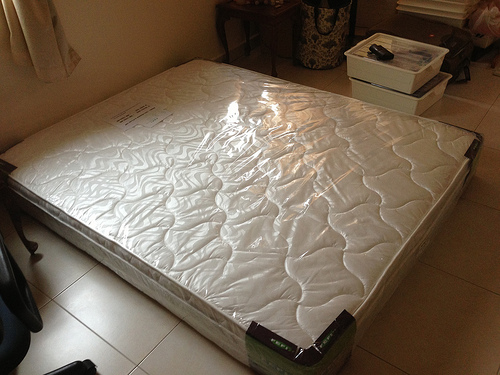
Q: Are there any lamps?
A: No, there are no lamps.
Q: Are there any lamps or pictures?
A: No, there are no lamps or pictures.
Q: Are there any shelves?
A: No, there are no shelves.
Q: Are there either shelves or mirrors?
A: No, there are no shelves or mirrors.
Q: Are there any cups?
A: No, there are no cups.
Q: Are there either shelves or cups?
A: No, there are no cups or shelves.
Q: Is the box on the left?
A: No, the box is on the right of the image.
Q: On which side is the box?
A: The box is on the right of the image.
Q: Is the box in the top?
A: Yes, the box is in the top of the image.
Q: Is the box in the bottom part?
A: No, the box is in the top of the image.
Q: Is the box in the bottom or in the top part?
A: The box is in the top of the image.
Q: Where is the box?
A: The box is on the floor.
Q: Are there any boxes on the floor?
A: Yes, there is a box on the floor.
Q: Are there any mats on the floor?
A: No, there is a box on the floor.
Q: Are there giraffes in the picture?
A: No, there are no giraffes.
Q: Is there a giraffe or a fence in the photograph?
A: No, there are no giraffes or fences.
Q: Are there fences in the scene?
A: No, there are no fences.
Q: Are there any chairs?
A: Yes, there is a chair.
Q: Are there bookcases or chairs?
A: Yes, there is a chair.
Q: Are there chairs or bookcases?
A: Yes, there is a chair.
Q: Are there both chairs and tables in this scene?
A: Yes, there are both a chair and a table.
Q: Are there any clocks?
A: No, there are no clocks.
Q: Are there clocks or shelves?
A: No, there are no clocks or shelves.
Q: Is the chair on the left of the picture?
A: Yes, the chair is on the left of the image.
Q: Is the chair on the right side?
A: No, the chair is on the left of the image.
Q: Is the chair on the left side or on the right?
A: The chair is on the left of the image.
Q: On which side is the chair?
A: The chair is on the left of the image.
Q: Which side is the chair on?
A: The chair is on the left of the image.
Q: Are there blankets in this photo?
A: No, there are no blankets.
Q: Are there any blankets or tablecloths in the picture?
A: No, there are no blankets or tablecloths.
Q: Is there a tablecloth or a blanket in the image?
A: No, there are no blankets or tablecloths.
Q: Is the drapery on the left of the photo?
A: Yes, the drapery is on the left of the image.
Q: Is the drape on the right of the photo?
A: No, the drape is on the left of the image.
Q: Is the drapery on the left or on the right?
A: The drapery is on the left of the image.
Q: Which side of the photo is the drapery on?
A: The drapery is on the left of the image.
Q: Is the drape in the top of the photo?
A: Yes, the drape is in the top of the image.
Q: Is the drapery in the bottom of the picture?
A: No, the drapery is in the top of the image.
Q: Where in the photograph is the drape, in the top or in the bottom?
A: The drape is in the top of the image.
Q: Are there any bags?
A: Yes, there is a bag.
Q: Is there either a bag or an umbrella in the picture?
A: Yes, there is a bag.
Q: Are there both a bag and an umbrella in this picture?
A: No, there is a bag but no umbrellas.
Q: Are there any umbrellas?
A: No, there are no umbrellas.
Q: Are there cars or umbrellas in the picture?
A: No, there are no umbrellas or cars.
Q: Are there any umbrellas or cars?
A: No, there are no umbrellas or cars.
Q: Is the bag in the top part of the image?
A: Yes, the bag is in the top of the image.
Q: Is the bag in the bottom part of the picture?
A: No, the bag is in the top of the image.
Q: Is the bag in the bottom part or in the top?
A: The bag is in the top of the image.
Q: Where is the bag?
A: The bag is on the floor.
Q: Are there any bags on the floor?
A: Yes, there is a bag on the floor.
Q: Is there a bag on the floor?
A: Yes, there is a bag on the floor.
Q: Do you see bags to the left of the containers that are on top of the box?
A: Yes, there is a bag to the left of the containers.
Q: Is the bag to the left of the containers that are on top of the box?
A: Yes, the bag is to the left of the containers.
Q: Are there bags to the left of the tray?
A: Yes, there is a bag to the left of the tray.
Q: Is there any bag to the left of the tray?
A: Yes, there is a bag to the left of the tray.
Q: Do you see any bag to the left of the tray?
A: Yes, there is a bag to the left of the tray.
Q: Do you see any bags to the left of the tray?
A: Yes, there is a bag to the left of the tray.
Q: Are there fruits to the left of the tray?
A: No, there is a bag to the left of the tray.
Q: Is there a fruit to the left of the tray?
A: No, there is a bag to the left of the tray.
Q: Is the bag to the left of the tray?
A: Yes, the bag is to the left of the tray.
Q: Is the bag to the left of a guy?
A: No, the bag is to the left of the tray.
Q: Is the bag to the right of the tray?
A: No, the bag is to the left of the tray.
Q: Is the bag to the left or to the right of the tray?
A: The bag is to the left of the tray.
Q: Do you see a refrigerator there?
A: No, there are no refrigerators.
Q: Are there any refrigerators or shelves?
A: No, there are no refrigerators or shelves.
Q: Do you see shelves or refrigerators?
A: No, there are no refrigerators or shelves.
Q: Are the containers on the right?
A: Yes, the containers are on the right of the image.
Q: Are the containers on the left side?
A: No, the containers are on the right of the image.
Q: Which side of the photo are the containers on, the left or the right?
A: The containers are on the right of the image.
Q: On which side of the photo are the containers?
A: The containers are on the right of the image.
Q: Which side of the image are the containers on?
A: The containers are on the right of the image.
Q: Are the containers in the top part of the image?
A: Yes, the containers are in the top of the image.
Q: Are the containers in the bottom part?
A: No, the containers are in the top of the image.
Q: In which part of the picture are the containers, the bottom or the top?
A: The containers are in the top of the image.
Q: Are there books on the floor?
A: No, there are containers on the floor.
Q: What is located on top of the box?
A: The containers are on top of the box.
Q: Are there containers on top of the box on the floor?
A: Yes, there are containers on top of the box.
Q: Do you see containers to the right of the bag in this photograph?
A: Yes, there are containers to the right of the bag.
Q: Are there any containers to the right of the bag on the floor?
A: Yes, there are containers to the right of the bag.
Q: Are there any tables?
A: Yes, there is a table.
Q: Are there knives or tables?
A: Yes, there is a table.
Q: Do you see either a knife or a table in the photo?
A: Yes, there is a table.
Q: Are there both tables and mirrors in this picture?
A: No, there is a table but no mirrors.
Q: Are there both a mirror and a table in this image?
A: No, there is a table but no mirrors.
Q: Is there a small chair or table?
A: Yes, there is a small table.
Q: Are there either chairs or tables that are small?
A: Yes, the table is small.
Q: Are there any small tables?
A: Yes, there is a small table.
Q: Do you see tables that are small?
A: Yes, there is a table that is small.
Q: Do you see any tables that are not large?
A: Yes, there is a small table.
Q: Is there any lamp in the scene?
A: No, there are no lamps.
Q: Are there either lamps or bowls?
A: No, there are no lamps or bowls.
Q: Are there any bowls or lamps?
A: No, there are no lamps or bowls.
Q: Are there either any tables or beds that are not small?
A: No, there is a table but it is small.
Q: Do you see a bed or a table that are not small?
A: No, there is a table but it is small.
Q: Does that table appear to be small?
A: Yes, the table is small.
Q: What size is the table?
A: The table is small.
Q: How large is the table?
A: The table is small.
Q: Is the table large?
A: No, the table is small.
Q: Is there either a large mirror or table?
A: No, there is a table but it is small.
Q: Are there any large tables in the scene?
A: No, there is a table but it is small.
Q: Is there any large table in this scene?
A: No, there is a table but it is small.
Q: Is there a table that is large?
A: No, there is a table but it is small.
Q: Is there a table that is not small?
A: No, there is a table but it is small.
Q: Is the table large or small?
A: The table is small.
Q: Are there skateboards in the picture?
A: No, there are no skateboards.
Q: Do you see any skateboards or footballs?
A: No, there are no skateboards or footballs.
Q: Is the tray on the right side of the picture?
A: Yes, the tray is on the right of the image.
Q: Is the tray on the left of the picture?
A: No, the tray is on the right of the image.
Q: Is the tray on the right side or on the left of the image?
A: The tray is on the right of the image.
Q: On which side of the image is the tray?
A: The tray is on the right of the image.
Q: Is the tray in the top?
A: Yes, the tray is in the top of the image.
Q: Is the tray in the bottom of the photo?
A: No, the tray is in the top of the image.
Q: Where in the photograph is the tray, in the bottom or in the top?
A: The tray is in the top of the image.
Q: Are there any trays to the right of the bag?
A: Yes, there is a tray to the right of the bag.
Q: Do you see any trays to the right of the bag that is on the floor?
A: Yes, there is a tray to the right of the bag.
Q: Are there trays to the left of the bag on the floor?
A: No, the tray is to the right of the bag.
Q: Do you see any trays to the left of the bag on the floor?
A: No, the tray is to the right of the bag.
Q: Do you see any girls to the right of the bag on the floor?
A: No, there is a tray to the right of the bag.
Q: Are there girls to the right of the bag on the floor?
A: No, there is a tray to the right of the bag.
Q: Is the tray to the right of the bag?
A: Yes, the tray is to the right of the bag.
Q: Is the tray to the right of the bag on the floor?
A: Yes, the tray is to the right of the bag.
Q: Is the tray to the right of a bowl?
A: No, the tray is to the right of the bag.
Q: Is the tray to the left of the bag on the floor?
A: No, the tray is to the right of the bag.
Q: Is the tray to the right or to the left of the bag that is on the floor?
A: The tray is to the right of the bag.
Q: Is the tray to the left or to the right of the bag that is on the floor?
A: The tray is to the right of the bag.